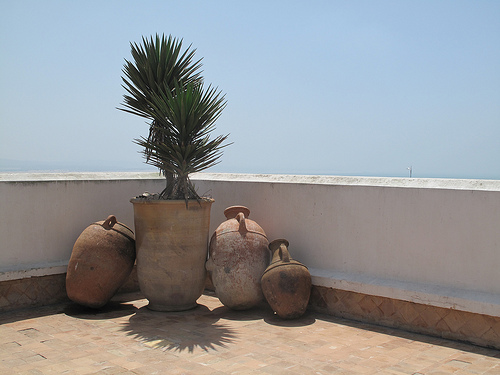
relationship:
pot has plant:
[128, 192, 211, 310] [116, 33, 232, 200]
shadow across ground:
[123, 300, 239, 355] [2, 283, 500, 373]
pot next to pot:
[64, 216, 138, 309] [128, 192, 211, 310]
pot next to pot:
[263, 238, 315, 319] [205, 203, 274, 309]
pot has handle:
[64, 216, 138, 309] [100, 214, 117, 230]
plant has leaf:
[116, 33, 232, 200] [169, 43, 195, 80]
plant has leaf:
[116, 33, 232, 200] [182, 58, 205, 78]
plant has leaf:
[116, 33, 232, 200] [193, 84, 209, 115]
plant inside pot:
[116, 33, 232, 200] [128, 192, 211, 310]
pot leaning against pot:
[263, 238, 315, 319] [205, 203, 274, 309]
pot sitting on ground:
[263, 238, 315, 319] [2, 283, 500, 373]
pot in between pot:
[128, 192, 211, 310] [64, 216, 138, 309]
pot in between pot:
[128, 192, 211, 310] [205, 203, 274, 309]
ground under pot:
[2, 283, 500, 373] [128, 192, 211, 310]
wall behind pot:
[2, 167, 499, 317] [128, 192, 211, 310]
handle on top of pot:
[100, 214, 117, 230] [64, 216, 138, 309]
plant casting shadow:
[116, 33, 232, 200] [123, 300, 239, 355]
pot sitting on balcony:
[64, 216, 138, 309] [0, 167, 499, 374]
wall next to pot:
[2, 167, 499, 317] [64, 216, 138, 309]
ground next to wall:
[2, 283, 500, 373] [2, 167, 499, 317]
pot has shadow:
[128, 192, 211, 310] [123, 300, 239, 355]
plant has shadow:
[116, 33, 232, 200] [123, 300, 239, 355]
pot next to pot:
[205, 203, 274, 309] [263, 238, 315, 319]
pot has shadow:
[64, 216, 138, 309] [63, 299, 139, 321]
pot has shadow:
[205, 203, 274, 309] [212, 300, 275, 322]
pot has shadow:
[263, 238, 315, 319] [263, 308, 319, 330]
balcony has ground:
[0, 167, 499, 374] [2, 283, 500, 373]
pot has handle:
[205, 203, 274, 309] [233, 211, 249, 231]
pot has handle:
[263, 238, 315, 319] [276, 243, 294, 263]